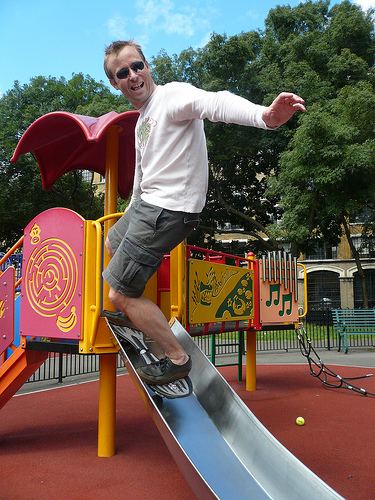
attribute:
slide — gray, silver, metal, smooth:
[96, 300, 344, 497]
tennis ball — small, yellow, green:
[286, 402, 311, 431]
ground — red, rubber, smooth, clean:
[223, 356, 373, 498]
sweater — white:
[102, 82, 268, 211]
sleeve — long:
[196, 84, 269, 140]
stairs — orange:
[5, 338, 50, 409]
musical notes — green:
[262, 281, 299, 317]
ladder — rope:
[295, 317, 369, 401]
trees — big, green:
[229, 4, 369, 247]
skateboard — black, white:
[109, 318, 200, 407]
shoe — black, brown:
[137, 355, 199, 384]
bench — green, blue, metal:
[328, 291, 369, 353]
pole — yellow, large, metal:
[91, 359, 121, 471]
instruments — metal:
[255, 243, 304, 290]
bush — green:
[6, 80, 95, 204]